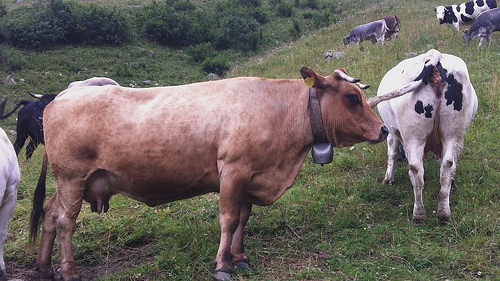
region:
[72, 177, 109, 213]
the utters on the cow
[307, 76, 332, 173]
the bell on the cows neck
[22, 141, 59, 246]
the brown cows tail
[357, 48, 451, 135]
the black and white cows tail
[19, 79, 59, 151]
the black bull in the back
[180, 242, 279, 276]
the front hooves of the brown cow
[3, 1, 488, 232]
all the cows in the photo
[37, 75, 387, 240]
the large brown cow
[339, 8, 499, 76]
the cows on the hill side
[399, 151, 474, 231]
the back hooves of the black and white cow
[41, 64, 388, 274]
a brown cow in a field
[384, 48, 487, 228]
a black and white cow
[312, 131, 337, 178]
a silver bell on a cow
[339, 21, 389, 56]
a gray cow in the field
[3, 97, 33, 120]
a black cows tail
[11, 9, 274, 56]
leafy green bushes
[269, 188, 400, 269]
green and brown grass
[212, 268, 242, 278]
a hoof on a cow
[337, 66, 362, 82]
a horn on a cow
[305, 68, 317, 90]
a yellow tag in a cows ear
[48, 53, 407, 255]
a big brown cow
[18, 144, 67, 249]
the tip of a cows tail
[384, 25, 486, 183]
the back side of a white and black cow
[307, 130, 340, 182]
a grey cow bell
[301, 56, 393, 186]
the head of a cow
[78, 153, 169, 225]
tits on a cow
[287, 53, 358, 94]
ear of a cow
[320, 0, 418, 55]
cows grazing in the field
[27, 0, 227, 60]
green bushes in the back ground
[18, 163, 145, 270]
the back legs on a cow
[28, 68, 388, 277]
Brown cow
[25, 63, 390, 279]
Bovine standing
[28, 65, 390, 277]
Brown cow wearing a bell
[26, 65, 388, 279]
Brown cow standing with a bell around neck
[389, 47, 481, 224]
Behind of a black and white cow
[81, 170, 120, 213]
Utters of a brown cow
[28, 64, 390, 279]
Tan colored cow with horns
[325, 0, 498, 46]
Group of cows standing on a hill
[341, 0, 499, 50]
Four cows standing on a hillside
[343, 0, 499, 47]
Several cows standing in grass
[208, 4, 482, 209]
cows on a hill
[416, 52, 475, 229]
the rear of a cow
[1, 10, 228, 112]
thick trees and bushes on a hill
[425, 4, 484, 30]
a cow looking towards the camera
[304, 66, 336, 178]
a cow bell around the cow's neck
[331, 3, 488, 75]
cows grazing in a grassy field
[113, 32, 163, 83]
large rocks next to the trees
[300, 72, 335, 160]
a silver cowbell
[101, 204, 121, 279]
a stream of urine